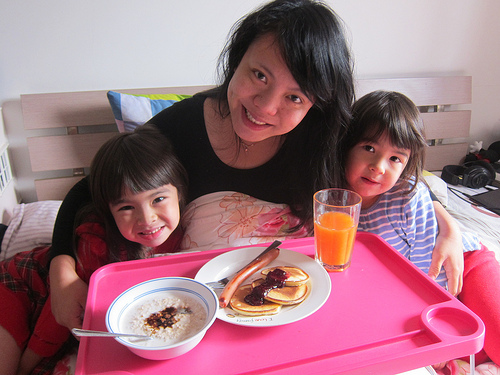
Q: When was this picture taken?
A: Daytime.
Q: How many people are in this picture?
A: Three.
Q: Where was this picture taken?
A: At the lunch table.